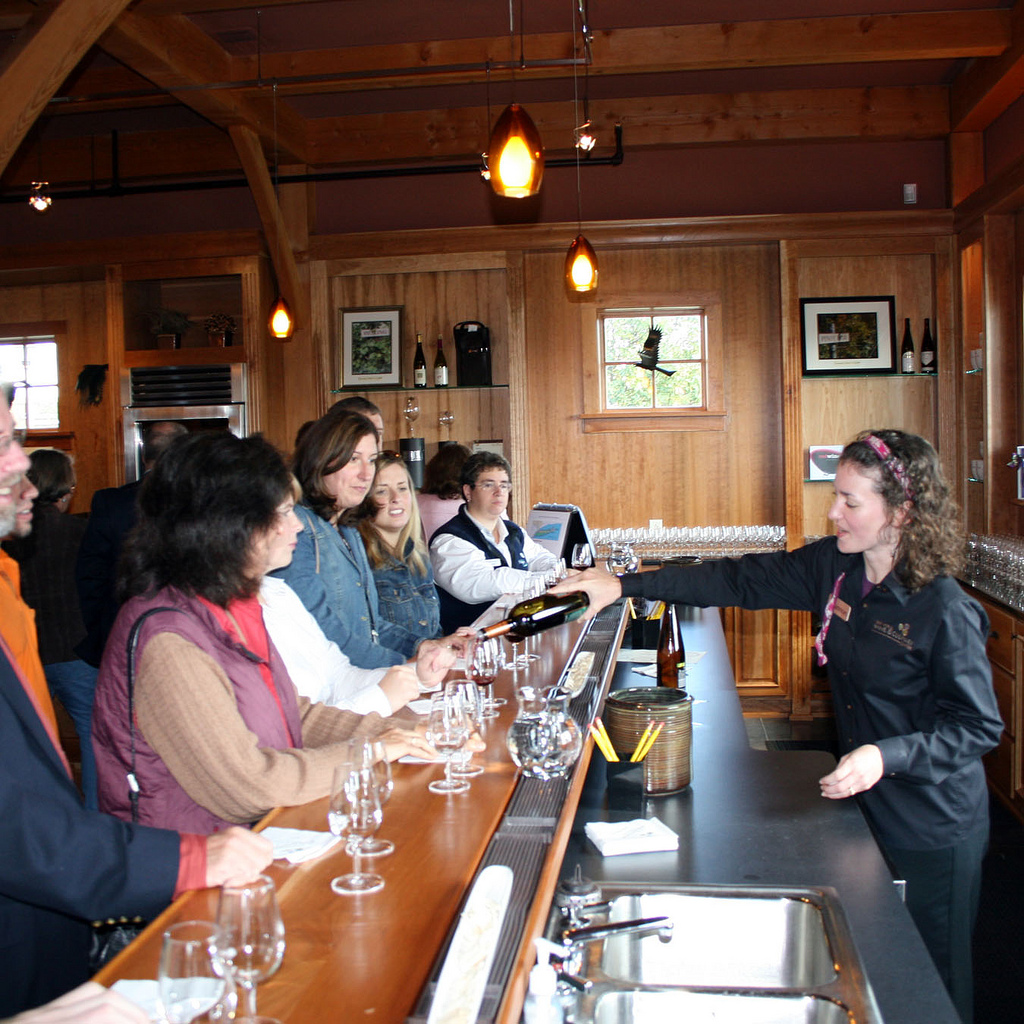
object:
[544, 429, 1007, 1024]
person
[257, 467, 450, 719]
person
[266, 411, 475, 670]
person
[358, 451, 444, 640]
person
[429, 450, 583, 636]
person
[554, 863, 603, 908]
drain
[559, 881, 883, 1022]
basin sink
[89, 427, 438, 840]
person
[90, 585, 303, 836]
vest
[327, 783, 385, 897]
glasses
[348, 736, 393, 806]
glasses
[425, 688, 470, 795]
glasses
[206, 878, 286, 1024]
glasses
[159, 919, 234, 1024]
glasses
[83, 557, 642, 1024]
bar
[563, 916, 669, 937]
faucet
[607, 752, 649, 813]
cup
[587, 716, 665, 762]
pencils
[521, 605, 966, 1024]
bartender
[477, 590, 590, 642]
bottle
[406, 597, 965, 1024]
black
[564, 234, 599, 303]
light hangs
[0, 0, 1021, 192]
ceiling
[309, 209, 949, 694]
walls